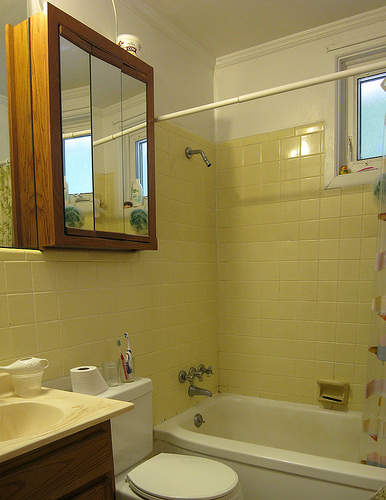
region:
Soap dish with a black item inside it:
[315, 376, 351, 407]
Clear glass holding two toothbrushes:
[115, 330, 137, 382]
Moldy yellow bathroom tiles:
[154, 363, 232, 428]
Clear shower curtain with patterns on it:
[362, 71, 384, 467]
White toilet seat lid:
[126, 451, 239, 498]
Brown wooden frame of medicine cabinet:
[1, 1, 155, 253]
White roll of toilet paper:
[70, 364, 109, 396]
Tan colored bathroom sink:
[0, 370, 136, 465]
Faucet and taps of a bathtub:
[177, 363, 217, 399]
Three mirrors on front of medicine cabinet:
[57, 33, 149, 238]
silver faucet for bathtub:
[187, 384, 209, 396]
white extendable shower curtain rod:
[153, 53, 380, 118]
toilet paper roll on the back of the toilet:
[69, 364, 109, 394]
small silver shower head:
[184, 146, 212, 169]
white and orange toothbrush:
[116, 339, 128, 380]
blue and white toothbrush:
[124, 329, 132, 373]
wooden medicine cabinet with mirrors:
[5, 2, 158, 252]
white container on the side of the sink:
[4, 353, 48, 394]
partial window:
[325, 43, 385, 183]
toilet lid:
[126, 451, 239, 498]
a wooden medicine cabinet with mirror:
[30, 4, 176, 256]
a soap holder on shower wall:
[309, 374, 365, 413]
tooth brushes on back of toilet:
[114, 318, 146, 387]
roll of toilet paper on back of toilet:
[70, 359, 114, 399]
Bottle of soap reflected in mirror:
[122, 166, 149, 213]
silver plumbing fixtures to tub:
[173, 350, 239, 406]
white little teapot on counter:
[4, 345, 50, 380]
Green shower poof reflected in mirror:
[126, 198, 157, 236]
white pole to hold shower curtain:
[160, 60, 385, 133]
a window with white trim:
[323, 47, 384, 166]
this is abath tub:
[144, 383, 372, 495]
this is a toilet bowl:
[123, 452, 233, 495]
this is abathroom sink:
[2, 359, 133, 453]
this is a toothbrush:
[117, 324, 136, 370]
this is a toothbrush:
[104, 325, 127, 383]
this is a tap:
[171, 365, 191, 386]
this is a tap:
[187, 359, 204, 393]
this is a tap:
[196, 358, 215, 385]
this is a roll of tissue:
[68, 364, 110, 405]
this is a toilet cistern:
[59, 361, 156, 475]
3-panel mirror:
[56, 32, 153, 232]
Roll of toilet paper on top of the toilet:
[67, 364, 112, 399]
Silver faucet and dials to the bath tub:
[175, 357, 217, 402]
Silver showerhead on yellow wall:
[185, 139, 212, 170]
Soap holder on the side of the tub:
[312, 374, 350, 410]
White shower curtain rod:
[155, 60, 383, 104]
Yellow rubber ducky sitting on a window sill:
[335, 163, 351, 176]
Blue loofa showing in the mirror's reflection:
[124, 201, 149, 234]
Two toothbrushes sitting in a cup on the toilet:
[110, 325, 141, 385]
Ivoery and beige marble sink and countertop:
[1, 386, 136, 453]